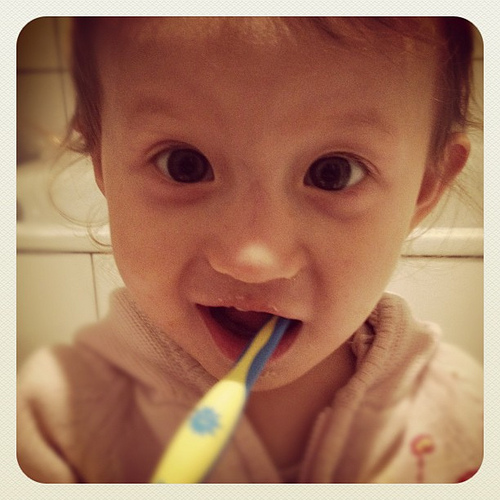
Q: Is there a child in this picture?
A: Yes, there is a child.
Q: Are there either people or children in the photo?
A: Yes, there is a child.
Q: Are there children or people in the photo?
A: Yes, there is a child.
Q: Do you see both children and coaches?
A: No, there is a child but no coaches.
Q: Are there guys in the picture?
A: No, there are no guys.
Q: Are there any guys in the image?
A: No, there are no guys.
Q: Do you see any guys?
A: No, there are no guys.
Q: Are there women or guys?
A: No, there are no guys or women.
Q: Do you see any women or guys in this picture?
A: No, there are no guys or women.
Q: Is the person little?
A: Yes, the kid is little.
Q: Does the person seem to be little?
A: Yes, the child is little.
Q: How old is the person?
A: The child is little.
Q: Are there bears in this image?
A: No, there are no bears.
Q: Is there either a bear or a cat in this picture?
A: No, there are no bears or cats.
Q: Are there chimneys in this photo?
A: No, there are no chimneys.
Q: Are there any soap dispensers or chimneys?
A: No, there are no chimneys or soap dispensers.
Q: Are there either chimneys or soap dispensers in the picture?
A: No, there are no chimneys or soap dispensers.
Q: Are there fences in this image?
A: No, there are no fences.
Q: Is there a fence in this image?
A: No, there are no fences.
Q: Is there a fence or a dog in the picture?
A: No, there are no fences or dogs.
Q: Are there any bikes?
A: No, there are no bikes.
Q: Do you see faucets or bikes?
A: No, there are no bikes or faucets.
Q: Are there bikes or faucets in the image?
A: No, there are no bikes or faucets.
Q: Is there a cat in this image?
A: No, there are no cats.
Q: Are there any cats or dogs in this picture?
A: No, there are no cats or dogs.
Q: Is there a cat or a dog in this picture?
A: No, there are no cats or dogs.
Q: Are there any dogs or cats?
A: No, there are no cats or dogs.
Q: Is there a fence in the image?
A: No, there are no fences.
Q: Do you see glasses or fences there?
A: No, there are no fences or glasses.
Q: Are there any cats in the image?
A: No, there are no cats.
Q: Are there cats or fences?
A: No, there are no cats or fences.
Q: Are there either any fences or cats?
A: No, there are no cats or fences.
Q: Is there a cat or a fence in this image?
A: No, there are no cats or fences.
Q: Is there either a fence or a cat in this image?
A: No, there are no cats or fences.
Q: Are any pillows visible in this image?
A: No, there are no pillows.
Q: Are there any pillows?
A: No, there are no pillows.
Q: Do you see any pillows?
A: No, there are no pillows.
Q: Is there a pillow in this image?
A: No, there are no pillows.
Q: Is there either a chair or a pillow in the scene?
A: No, there are no pillows or chairs.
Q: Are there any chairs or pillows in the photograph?
A: No, there are no pillows or chairs.